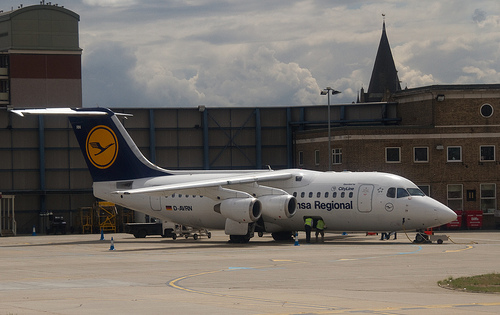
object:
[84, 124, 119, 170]
logo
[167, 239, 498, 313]
lines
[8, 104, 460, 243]
plane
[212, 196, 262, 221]
engines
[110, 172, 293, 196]
wing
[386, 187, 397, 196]
window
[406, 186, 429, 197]
windshield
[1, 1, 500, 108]
sky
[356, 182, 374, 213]
door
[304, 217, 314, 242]
workers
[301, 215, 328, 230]
luggage compartment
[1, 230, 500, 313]
tarmac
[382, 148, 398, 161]
window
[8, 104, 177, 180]
tail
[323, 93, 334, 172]
light pole